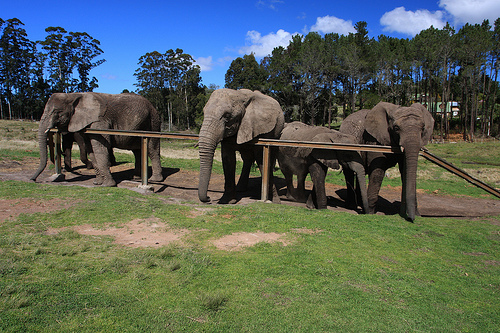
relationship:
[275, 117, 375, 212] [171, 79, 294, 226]
animal between elephant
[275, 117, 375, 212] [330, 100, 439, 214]
animal between elephant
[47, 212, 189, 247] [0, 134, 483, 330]
dirt in grass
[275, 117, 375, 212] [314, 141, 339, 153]
animal on rail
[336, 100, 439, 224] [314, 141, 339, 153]
animal on rail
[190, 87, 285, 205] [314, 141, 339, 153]
animal on rail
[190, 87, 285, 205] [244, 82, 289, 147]
animal has ear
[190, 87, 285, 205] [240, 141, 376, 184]
animal behind rail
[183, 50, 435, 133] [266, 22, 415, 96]
row of trees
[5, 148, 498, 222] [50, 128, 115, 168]
trail behind elephant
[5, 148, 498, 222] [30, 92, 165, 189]
trail behind animal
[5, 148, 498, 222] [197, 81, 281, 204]
trail behind elephant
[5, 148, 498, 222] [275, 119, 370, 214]
trail behind elephant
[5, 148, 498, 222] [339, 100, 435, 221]
trail behind elephant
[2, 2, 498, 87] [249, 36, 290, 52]
sky with clouds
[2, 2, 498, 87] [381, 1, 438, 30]
sky with clouds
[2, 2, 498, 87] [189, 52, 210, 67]
sky with clouds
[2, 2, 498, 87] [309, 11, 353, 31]
sky with clouds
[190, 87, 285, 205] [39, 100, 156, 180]
animal next to elephant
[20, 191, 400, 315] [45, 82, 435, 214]
grass near elephants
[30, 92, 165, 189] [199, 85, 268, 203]
animal near elephant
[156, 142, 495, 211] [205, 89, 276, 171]
fence in front of elephant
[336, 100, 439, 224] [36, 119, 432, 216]
animal are behind fence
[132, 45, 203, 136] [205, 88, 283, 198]
tree behind elephant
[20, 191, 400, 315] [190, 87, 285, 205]
grass in front of animal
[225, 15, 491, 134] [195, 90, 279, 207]
tree line behind elephant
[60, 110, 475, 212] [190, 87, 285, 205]
barrier in front of animal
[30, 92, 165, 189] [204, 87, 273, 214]
animal next to elephant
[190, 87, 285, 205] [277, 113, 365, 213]
animal next to elephant